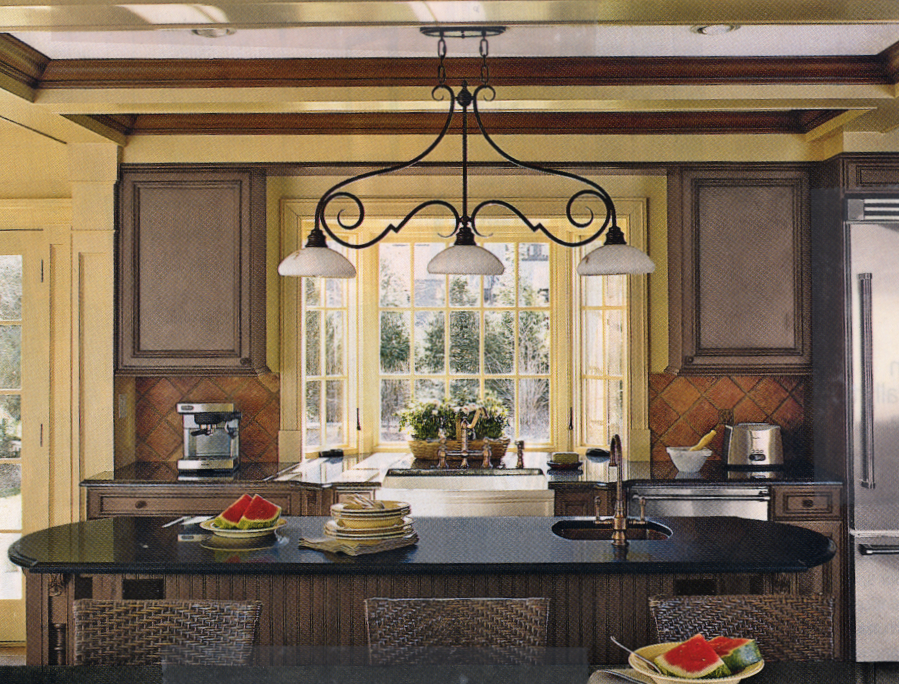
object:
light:
[278, 26, 657, 278]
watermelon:
[653, 633, 762, 679]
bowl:
[627, 641, 765, 684]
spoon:
[610, 635, 662, 674]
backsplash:
[135, 373, 281, 463]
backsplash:
[648, 372, 812, 461]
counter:
[548, 455, 845, 489]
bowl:
[666, 446, 714, 473]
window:
[300, 215, 628, 461]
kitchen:
[0, 0, 899, 684]